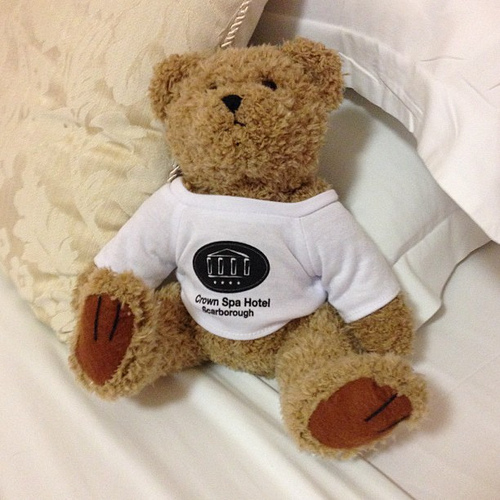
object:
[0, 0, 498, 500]
bed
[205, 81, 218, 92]
eye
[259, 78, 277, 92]
eye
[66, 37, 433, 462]
doll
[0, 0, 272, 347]
pillow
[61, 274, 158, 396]
foot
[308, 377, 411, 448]
sole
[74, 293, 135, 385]
sole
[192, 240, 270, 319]
graphic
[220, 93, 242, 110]
nose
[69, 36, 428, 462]
bear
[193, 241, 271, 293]
picture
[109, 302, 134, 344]
toes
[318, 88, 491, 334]
pillow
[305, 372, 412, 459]
paddings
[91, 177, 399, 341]
shirt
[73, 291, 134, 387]
bottom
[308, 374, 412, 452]
bottom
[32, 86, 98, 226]
pattern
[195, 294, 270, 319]
lettering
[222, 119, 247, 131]
mouth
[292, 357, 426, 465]
feet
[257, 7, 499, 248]
pillow